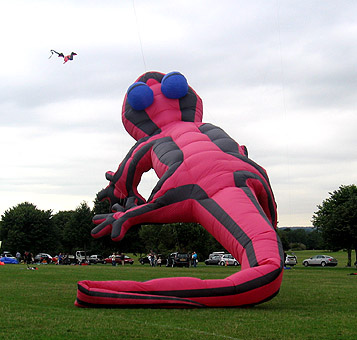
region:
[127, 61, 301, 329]
large blow up lizard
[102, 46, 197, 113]
lizard has large blue eyes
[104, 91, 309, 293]
red and black lizard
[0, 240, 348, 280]
many cars parked on grass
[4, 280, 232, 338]
white line in grass of photo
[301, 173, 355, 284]
silver car parked by tree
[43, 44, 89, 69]
kite flying in sky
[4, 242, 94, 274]
people near vehicles in background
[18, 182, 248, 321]
tail of lizard on ground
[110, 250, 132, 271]
people near red car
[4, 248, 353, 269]
cars on the green grass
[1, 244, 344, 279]
people on the green grass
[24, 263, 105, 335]
the grass is in a field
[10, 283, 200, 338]
the grass has been cut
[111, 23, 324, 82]
the sky is cloudy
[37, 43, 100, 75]
a balloon in the sky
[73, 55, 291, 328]
a balloon on the grass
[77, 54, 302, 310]
the balloon is red and black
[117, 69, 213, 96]
the balloon has blue eyes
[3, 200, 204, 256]
trees with green leaves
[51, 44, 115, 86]
kite flyin above ground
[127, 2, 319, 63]
white strings in air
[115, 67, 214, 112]
blue colored eye balls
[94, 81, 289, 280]
red and black lizard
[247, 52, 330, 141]
sky filled with fluffy clouds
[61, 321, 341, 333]
freshly cut green grass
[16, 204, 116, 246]
dark green colored trees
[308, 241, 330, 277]
silver colored sedan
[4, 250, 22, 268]
blue tarp on ground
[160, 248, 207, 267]
black large SUV parked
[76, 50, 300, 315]
a large lizard balloon.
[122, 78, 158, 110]
the eyes are royal blue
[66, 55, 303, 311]
its body is pink and black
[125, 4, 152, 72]
one of the wires that holds it up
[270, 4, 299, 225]
the cable is gray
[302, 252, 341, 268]
a gray car is parked on the road side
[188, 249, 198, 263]
a person is standing by the road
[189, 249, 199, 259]
the person is wearing a blue shirt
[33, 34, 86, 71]
another balloon kite is in the air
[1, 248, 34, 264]
the people are standing around a blue object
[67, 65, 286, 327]
Red and black lizard balloon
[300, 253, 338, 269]
Car parked beside the road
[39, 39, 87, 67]
Balloon flying in the air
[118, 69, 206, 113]
Blue eyes on lizard balloon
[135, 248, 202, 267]
People standing beside vehicles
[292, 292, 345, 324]
Green grass on the ground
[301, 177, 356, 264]
Car parked beside a tree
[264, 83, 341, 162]
Cloudy sky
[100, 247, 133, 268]
People standing beside a red car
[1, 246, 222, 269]
Row of people and cars